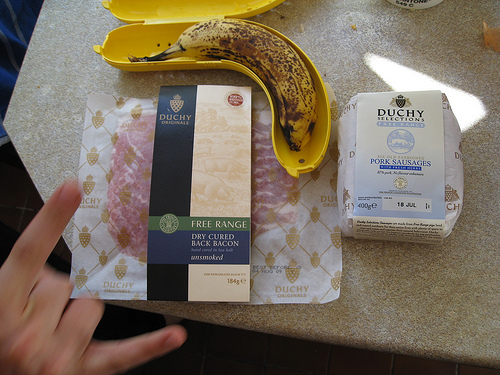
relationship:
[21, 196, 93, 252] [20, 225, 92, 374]
finger of person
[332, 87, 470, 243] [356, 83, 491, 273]
package of sausages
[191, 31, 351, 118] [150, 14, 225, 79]
banana in case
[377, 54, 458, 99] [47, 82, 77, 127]
light on table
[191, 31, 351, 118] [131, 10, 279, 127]
banana in container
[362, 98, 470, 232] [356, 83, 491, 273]
package of sausages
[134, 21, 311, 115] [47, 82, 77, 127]
food on table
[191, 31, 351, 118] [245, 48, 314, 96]
banana has spots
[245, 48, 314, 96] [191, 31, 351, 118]
spots on banana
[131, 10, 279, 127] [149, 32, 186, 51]
container has holes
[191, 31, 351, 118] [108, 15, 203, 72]
banana in holder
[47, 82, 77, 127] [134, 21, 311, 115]
table with food